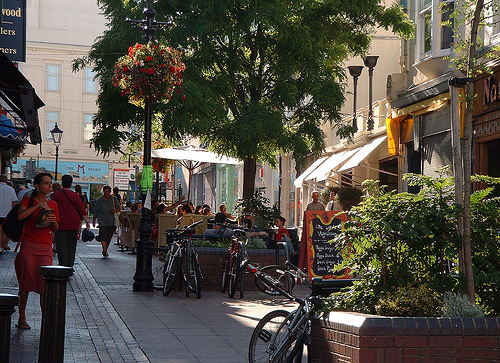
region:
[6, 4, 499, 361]
the city square is busy with activity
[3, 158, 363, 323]
people are walking near the shops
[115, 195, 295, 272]
people are sitting at tables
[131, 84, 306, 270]
the tables are under the trees and umbrellas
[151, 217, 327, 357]
bikes are parked everywhere in the square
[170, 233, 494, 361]
red brick planters are in the center of the area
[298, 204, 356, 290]
a sidewalk sign is in front of the area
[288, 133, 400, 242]
awnings are over the front of the store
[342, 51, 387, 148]
black decorative sconces are above the awnings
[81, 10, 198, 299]
a hanging flowering plant is in the square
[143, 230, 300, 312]
Bicycles parked by the tree.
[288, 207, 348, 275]
A posterboard on the sidewalk.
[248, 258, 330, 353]
A bicycle leaning against the step.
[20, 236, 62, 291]
The woman is wearing a red skirt.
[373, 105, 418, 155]
Yellow flag on the store.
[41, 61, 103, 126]
Windows on the building.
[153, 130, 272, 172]
The white umbrella on sidewalk.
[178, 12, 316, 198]
A tree in the middle of sidewalk.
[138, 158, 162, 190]
Green sign on the pole.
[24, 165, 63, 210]
the head of a woman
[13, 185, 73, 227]
the arm of a woman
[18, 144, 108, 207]
the hair of a woman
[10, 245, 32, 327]
the leg of a woman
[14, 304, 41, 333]
the foot of a woman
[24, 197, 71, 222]
the hand of a woman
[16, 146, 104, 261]
a woman wearing a red shirt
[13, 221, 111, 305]
a woman wearing a dress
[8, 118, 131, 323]
a woman walking down the street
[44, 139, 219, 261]
people in the background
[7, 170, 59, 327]
woman in red walking around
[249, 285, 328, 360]
bike leaning against brick structure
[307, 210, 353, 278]
sign standing on sidewalk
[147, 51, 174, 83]
red flowers on plant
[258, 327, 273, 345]
left pedal on bike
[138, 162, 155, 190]
green poster on black pole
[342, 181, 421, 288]
green leaves on plant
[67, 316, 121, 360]
brick walkway on the ground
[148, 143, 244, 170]
white umbrella on pole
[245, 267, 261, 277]
red reflector on bike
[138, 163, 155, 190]
Green sign on a small pole.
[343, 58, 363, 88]
Green sign on a small pole.